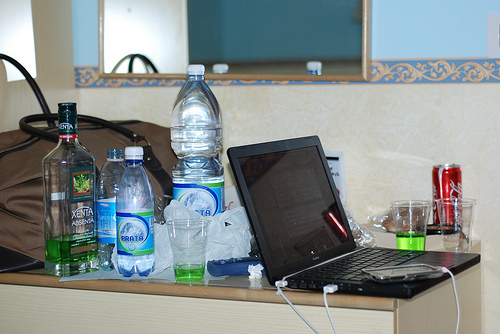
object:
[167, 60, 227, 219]
bottle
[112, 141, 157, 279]
bottle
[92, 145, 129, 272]
bottle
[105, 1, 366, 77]
mirror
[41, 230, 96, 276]
bottle liquor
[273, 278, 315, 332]
cord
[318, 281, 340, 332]
cord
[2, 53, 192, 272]
bag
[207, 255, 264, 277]
remote controller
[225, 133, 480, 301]
black laptop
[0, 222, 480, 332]
table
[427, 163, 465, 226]
can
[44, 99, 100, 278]
bottle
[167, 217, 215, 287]
cup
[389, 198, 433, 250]
cup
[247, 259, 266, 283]
paper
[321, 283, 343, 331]
plug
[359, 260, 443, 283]
phone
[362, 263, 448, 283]
device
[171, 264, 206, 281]
liquid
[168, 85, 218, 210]
water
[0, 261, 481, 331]
counter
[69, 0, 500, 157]
wall